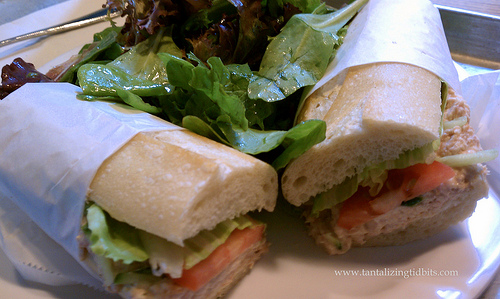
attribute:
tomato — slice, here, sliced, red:
[205, 254, 226, 267]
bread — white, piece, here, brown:
[304, 101, 403, 168]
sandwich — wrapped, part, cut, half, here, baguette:
[292, 98, 444, 246]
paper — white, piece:
[373, 8, 442, 57]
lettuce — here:
[88, 219, 125, 258]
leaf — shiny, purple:
[1, 59, 34, 88]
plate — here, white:
[459, 271, 489, 290]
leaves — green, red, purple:
[250, 0, 322, 85]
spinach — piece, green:
[301, 5, 334, 17]